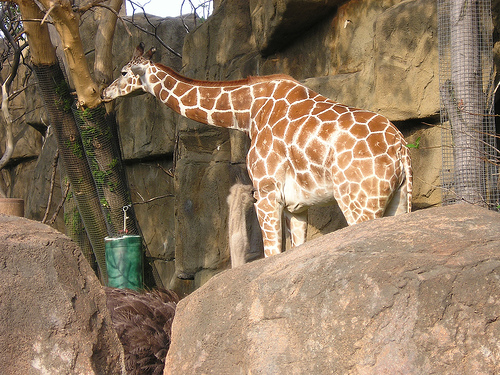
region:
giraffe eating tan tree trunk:
[77, 40, 413, 246]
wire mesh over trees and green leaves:
[66, 105, 136, 237]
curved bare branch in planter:
[0, 5, 30, 210]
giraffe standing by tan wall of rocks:
[1, 0, 446, 287]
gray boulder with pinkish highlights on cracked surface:
[165, 200, 495, 370]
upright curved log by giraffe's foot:
[225, 180, 250, 260]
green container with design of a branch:
[100, 235, 140, 290]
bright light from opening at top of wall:
[120, 0, 210, 16]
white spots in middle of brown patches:
[246, 140, 386, 177]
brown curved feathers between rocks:
[95, 282, 176, 370]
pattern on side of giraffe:
[287, 115, 339, 157]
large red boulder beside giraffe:
[191, 230, 488, 372]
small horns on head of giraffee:
[129, 39, 164, 62]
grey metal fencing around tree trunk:
[430, 11, 497, 200]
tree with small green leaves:
[77, 139, 123, 204]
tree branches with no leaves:
[0, 0, 35, 125]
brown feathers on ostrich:
[121, 290, 171, 352]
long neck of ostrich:
[212, 179, 259, 275]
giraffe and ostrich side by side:
[25, 48, 442, 365]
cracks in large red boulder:
[419, 251, 497, 341]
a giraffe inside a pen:
[90, 46, 431, 260]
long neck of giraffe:
[148, 66, 250, 133]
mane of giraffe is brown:
[156, 55, 291, 88]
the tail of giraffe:
[401, 145, 421, 217]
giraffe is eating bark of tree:
[27, 5, 168, 192]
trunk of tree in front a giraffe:
[17, 6, 152, 286]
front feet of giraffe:
[253, 201, 304, 261]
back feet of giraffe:
[330, 197, 410, 236]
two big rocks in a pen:
[2, 198, 498, 374]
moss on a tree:
[71, 106, 125, 205]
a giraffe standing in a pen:
[98, 48, 426, 252]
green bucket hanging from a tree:
[101, 215, 151, 291]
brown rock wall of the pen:
[352, 1, 421, 93]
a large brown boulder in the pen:
[265, 251, 496, 348]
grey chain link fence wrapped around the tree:
[431, 3, 493, 206]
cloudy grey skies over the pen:
[148, 0, 173, 17]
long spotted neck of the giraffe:
[138, 63, 268, 132]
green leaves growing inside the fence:
[28, 92, 135, 249]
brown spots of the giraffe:
[281, 125, 339, 168]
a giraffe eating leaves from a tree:
[85, 53, 205, 133]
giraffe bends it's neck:
[100, 42, 413, 261]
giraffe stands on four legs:
[97, 41, 414, 257]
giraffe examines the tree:
[103, 43, 415, 258]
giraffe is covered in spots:
[104, 41, 414, 259]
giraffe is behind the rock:
[99, 43, 414, 263]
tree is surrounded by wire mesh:
[437, 3, 499, 210]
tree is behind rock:
[12, 0, 157, 292]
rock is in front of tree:
[0, 211, 125, 371]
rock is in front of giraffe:
[154, 197, 497, 374]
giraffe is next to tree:
[98, 42, 415, 255]